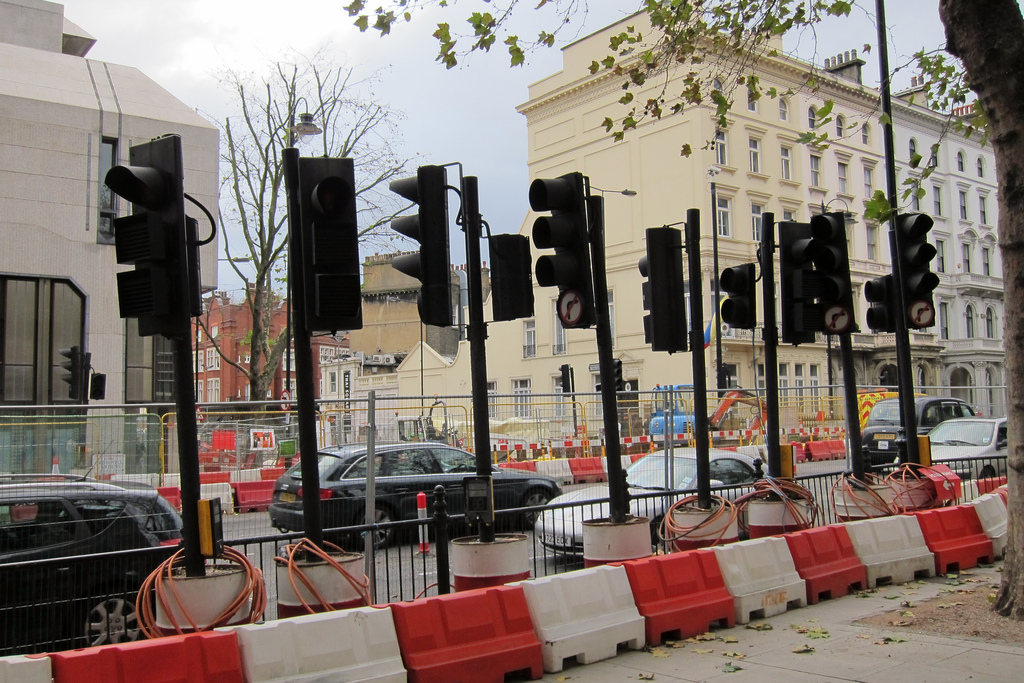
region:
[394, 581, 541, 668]
A orange barrier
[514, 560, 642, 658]
A white barrier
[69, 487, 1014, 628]
The group of orange and white barriers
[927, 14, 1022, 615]
A brown tree trunk near the barrier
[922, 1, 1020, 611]
The brown tree barrier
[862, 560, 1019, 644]
The mound of dirt under the tree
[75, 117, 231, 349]
The black traffic light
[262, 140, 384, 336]
A black traffic light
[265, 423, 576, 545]
car is black in color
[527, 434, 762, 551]
car is silver in color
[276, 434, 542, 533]
car is on the street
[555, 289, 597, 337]
sign is red and white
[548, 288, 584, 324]
sign has arrow on it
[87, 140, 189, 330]
streetlights are on the road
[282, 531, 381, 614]
cords are orange in color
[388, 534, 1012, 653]
red and white barrier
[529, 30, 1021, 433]
building is tall and white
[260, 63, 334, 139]
streetlight is on pole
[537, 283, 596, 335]
red and white sign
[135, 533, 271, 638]
cords are orange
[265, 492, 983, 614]
barrier is red and white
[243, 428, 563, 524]
car on street is black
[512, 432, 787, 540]
car parked is white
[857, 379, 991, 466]
van is black in color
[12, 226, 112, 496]
window on side of building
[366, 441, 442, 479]
window on side of car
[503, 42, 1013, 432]
building is light yellow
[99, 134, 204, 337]
a portable electric traffic signal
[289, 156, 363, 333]
a portable electric traffic signal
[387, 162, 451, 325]
a portable electric traffic signal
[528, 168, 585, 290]
a portable electric traffic signal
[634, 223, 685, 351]
a portable electric traffic signal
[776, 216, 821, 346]
a portable electric traffic signala portable electric traffic signal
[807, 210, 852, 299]
a portable electric traffic signal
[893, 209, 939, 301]
a portable electric traffic signal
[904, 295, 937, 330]
a no right turn sign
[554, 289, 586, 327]
a no right turn sign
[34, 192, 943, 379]
A lot of black stoplight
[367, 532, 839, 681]
a red and white wall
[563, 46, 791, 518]
A tall tan building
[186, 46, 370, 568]
A tree with no leave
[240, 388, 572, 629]
a black car parked on the street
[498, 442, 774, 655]
a white car parked on the street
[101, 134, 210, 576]
traffic light is black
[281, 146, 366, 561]
traffic light is black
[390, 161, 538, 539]
traffic light is black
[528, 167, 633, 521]
traffic light is black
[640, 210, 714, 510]
traffic light is black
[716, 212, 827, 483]
traffic light is black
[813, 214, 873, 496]
traffic light is black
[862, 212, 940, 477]
traffic light is black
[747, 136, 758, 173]
window facing busy intersection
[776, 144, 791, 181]
window facing busy intersection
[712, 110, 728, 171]
glass window on building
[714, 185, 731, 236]
glass window on building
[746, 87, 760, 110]
glass window on building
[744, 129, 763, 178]
glass window on building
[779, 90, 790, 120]
glass window on building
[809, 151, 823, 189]
glass window on building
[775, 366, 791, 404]
glass window on building